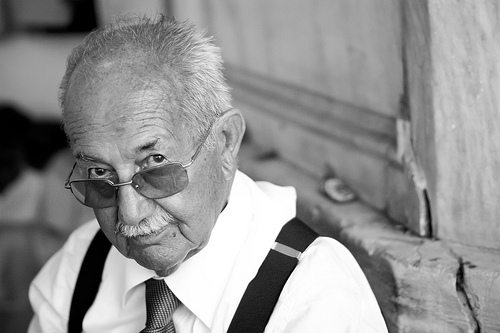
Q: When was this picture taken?
A: No indication of when.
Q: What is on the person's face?
A: Sunglasses.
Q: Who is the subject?
A: Elderly man.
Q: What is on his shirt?
A: Suspenders.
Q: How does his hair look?
A: Gray with receding hairline.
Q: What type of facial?
A: Mustache.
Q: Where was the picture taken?
A: No indication of where.